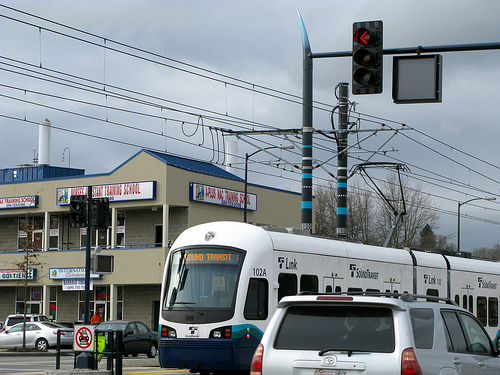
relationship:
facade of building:
[4, 153, 166, 369] [6, 131, 316, 353]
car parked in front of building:
[0, 320, 71, 350] [2, 146, 315, 331]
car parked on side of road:
[249, 295, 500, 375] [27, 332, 167, 372]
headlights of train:
[166, 324, 226, 345] [145, 240, 497, 352]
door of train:
[268, 267, 318, 305] [153, 220, 438, 373]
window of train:
[272, 270, 321, 301] [151, 217, 497, 371]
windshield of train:
[162, 244, 245, 325] [151, 217, 497, 371]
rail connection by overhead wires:
[347, 161, 410, 246] [0, 4, 499, 224]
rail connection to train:
[347, 161, 410, 246] [151, 217, 497, 371]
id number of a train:
[247, 264, 277, 279] [151, 217, 497, 371]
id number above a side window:
[247, 264, 277, 279] [239, 277, 270, 320]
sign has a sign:
[73, 325, 103, 359] [73, 325, 103, 359]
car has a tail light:
[254, 275, 496, 367] [245, 338, 265, 371]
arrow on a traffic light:
[352, 25, 379, 48] [351, 19, 383, 94]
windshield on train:
[154, 242, 247, 332] [151, 217, 497, 371]